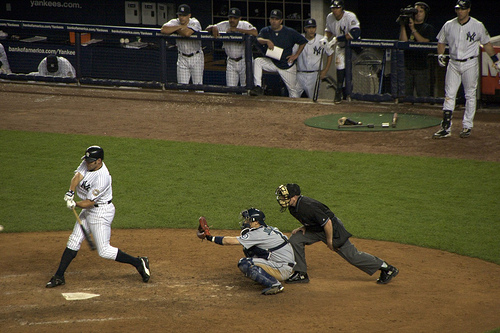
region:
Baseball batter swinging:
[42, 142, 150, 289]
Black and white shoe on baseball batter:
[132, 252, 152, 279]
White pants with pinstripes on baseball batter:
[62, 198, 115, 259]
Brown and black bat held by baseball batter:
[66, 201, 96, 252]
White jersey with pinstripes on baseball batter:
[73, 160, 113, 202]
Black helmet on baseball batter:
[80, 141, 106, 162]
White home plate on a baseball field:
[60, 287, 105, 300]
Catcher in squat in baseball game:
[207, 207, 297, 294]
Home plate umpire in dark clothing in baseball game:
[275, 180, 398, 282]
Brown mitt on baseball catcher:
[194, 210, 210, 244]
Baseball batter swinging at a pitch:
[43, 142, 163, 296]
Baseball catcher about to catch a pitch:
[193, 205, 299, 296]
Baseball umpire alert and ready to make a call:
[268, 173, 406, 297]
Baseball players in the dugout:
[157, 0, 375, 97]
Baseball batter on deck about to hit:
[435, 0, 490, 142]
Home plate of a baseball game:
[59, 285, 101, 307]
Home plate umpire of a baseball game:
[273, 171, 408, 292]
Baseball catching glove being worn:
[191, 213, 220, 253]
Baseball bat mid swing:
[64, 199, 106, 256]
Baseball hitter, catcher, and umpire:
[50, 132, 412, 299]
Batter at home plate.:
[42, 144, 153, 306]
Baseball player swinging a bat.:
[43, 145, 150, 290]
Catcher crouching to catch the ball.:
[196, 204, 297, 297]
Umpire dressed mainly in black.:
[272, 174, 400, 294]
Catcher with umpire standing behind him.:
[194, 176, 399, 295]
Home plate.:
[59, 288, 101, 300]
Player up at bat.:
[45, 140, 150, 285]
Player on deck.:
[426, 1, 496, 141]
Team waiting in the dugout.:
[162, 0, 360, 103]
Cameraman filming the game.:
[390, 0, 435, 106]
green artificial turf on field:
[138, 162, 249, 203]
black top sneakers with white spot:
[364, 255, 421, 286]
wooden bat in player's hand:
[65, 202, 103, 234]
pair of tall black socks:
[36, 242, 166, 287]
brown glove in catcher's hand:
[189, 213, 223, 244]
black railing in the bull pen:
[87, 19, 297, 47]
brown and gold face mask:
[269, 179, 307, 213]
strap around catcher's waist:
[234, 218, 299, 261]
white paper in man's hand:
[254, 30, 306, 65]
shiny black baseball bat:
[306, 39, 336, 119]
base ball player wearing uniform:
[57, 131, 119, 299]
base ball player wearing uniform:
[190, 193, 298, 295]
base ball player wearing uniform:
[268, 176, 395, 258]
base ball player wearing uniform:
[427, 3, 488, 123]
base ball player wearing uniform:
[282, 35, 323, 90]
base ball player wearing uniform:
[167, 12, 237, 107]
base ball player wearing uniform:
[204, 13, 251, 88]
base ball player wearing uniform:
[37, 41, 89, 93]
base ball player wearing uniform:
[318, 11, 365, 28]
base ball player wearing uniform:
[217, 5, 259, 33]